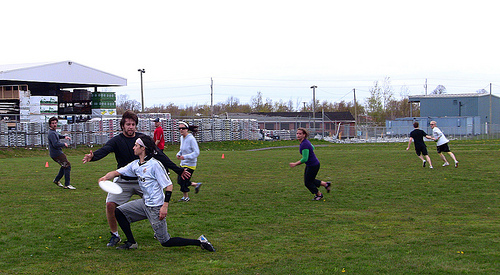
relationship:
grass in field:
[244, 194, 317, 239] [46, 147, 490, 247]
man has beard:
[426, 118, 472, 174] [431, 125, 439, 128]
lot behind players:
[30, 85, 288, 158] [32, 106, 439, 245]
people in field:
[71, 103, 351, 251] [46, 147, 490, 247]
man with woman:
[426, 118, 472, 174] [163, 115, 207, 196]